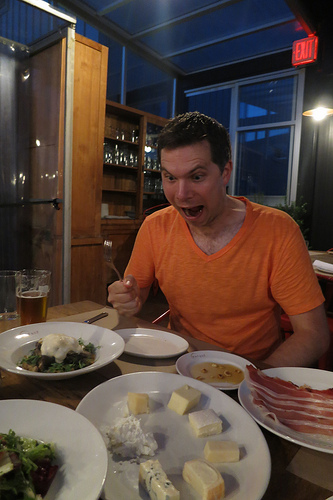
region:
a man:
[102, 103, 327, 364]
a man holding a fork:
[99, 111, 332, 361]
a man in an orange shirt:
[99, 111, 325, 368]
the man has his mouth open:
[145, 121, 260, 231]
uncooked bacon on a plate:
[248, 359, 332, 452]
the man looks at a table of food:
[20, 113, 323, 490]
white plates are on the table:
[5, 319, 323, 498]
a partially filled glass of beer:
[12, 267, 60, 339]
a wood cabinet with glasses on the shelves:
[99, 93, 179, 288]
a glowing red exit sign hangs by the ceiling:
[286, 31, 320, 70]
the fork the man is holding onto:
[99, 237, 125, 284]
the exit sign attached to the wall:
[288, 39, 315, 66]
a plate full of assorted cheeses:
[75, 372, 271, 499]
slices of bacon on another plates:
[245, 363, 332, 440]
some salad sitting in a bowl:
[2, 431, 51, 495]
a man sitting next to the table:
[111, 116, 332, 364]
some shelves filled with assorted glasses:
[102, 106, 168, 228]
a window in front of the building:
[178, 85, 306, 201]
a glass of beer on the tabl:
[19, 266, 52, 322]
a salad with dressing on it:
[17, 334, 85, 373]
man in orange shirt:
[90, 96, 312, 358]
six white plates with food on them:
[1, 304, 319, 490]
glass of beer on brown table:
[9, 253, 86, 359]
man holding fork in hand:
[64, 229, 161, 345]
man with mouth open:
[150, 117, 242, 233]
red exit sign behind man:
[289, 27, 331, 102]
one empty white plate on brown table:
[78, 296, 197, 376]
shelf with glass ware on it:
[100, 101, 165, 254]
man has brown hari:
[150, 113, 239, 214]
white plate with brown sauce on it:
[179, 350, 259, 408]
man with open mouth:
[152, 109, 254, 234]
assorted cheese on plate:
[131, 386, 232, 492]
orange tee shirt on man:
[128, 198, 301, 335]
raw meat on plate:
[244, 367, 320, 423]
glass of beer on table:
[14, 265, 56, 329]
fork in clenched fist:
[98, 235, 142, 315]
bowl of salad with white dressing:
[18, 320, 114, 378]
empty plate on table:
[104, 322, 192, 363]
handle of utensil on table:
[79, 306, 113, 329]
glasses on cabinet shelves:
[101, 131, 151, 197]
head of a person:
[145, 109, 241, 236]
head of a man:
[137, 111, 241, 232]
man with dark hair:
[146, 109, 244, 249]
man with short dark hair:
[141, 106, 240, 240]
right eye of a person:
[158, 167, 177, 186]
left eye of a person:
[188, 171, 207, 190]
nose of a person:
[170, 177, 195, 203]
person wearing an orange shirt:
[106, 85, 321, 348]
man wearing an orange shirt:
[97, 102, 322, 356]